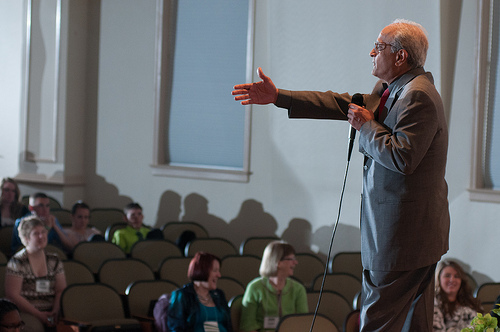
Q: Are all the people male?
A: No, they are both male and female.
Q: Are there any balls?
A: No, there are no balls.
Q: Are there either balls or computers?
A: No, there are no balls or computers.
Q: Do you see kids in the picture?
A: No, there are no kids.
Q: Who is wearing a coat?
A: The man is wearing a coat.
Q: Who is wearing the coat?
A: The man is wearing a coat.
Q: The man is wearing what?
A: The man is wearing a coat.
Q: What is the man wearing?
A: The man is wearing a coat.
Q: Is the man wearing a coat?
A: Yes, the man is wearing a coat.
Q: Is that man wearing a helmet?
A: No, the man is wearing a coat.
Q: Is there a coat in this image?
A: Yes, there is a coat.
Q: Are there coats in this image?
A: Yes, there is a coat.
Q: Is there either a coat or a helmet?
A: Yes, there is a coat.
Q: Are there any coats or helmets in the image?
A: Yes, there is a coat.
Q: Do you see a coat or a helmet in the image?
A: Yes, there is a coat.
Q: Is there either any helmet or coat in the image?
A: Yes, there is a coat.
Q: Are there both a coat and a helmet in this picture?
A: No, there is a coat but no helmets.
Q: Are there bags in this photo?
A: No, there are no bags.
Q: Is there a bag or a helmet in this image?
A: No, there are no bags or helmets.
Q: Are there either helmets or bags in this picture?
A: No, there are no bags or helmets.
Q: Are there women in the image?
A: Yes, there are women.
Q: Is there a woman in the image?
A: Yes, there are women.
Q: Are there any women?
A: Yes, there are women.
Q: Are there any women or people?
A: Yes, there are women.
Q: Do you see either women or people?
A: Yes, there are women.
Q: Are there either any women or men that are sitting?
A: Yes, the women are sitting.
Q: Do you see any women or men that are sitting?
A: Yes, the women are sitting.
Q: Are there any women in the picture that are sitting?
A: Yes, there are women that are sitting.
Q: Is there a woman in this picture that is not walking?
A: Yes, there are women that are sitting.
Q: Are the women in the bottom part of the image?
A: Yes, the women are in the bottom of the image.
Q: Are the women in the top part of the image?
A: No, the women are in the bottom of the image.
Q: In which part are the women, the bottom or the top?
A: The women are in the bottom of the image.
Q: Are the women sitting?
A: Yes, the women are sitting.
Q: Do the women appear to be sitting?
A: Yes, the women are sitting.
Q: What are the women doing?
A: The women are sitting.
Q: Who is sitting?
A: The women are sitting.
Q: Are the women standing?
A: No, the women are sitting.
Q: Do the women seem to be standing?
A: No, the women are sitting.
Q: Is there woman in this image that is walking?
A: No, there are women but they are sitting.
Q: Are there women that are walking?
A: No, there are women but they are sitting.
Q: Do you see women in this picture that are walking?
A: No, there are women but they are sitting.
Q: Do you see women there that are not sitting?
A: No, there are women but they are sitting.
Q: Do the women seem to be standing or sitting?
A: The women are sitting.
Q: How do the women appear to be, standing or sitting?
A: The women are sitting.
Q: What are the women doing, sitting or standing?
A: The women are sitting.